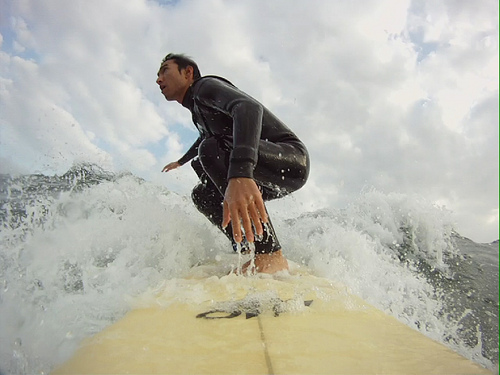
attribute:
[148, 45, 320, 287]
surfer — crouched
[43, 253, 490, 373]
surfboard — white, yellow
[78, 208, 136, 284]
waves — violent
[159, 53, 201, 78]
black hair — short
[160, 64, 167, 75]
eyes — looking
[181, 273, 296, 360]
board — yellow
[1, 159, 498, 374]
waves — white, grey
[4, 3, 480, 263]
sky — cloudy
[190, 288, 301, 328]
writing — black